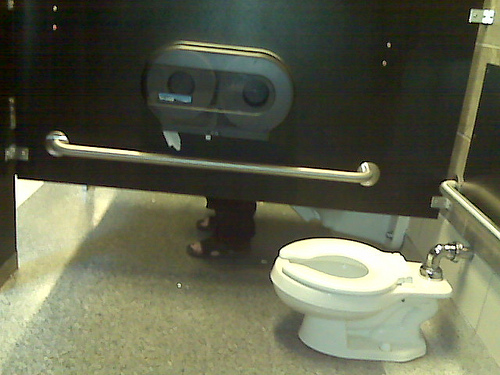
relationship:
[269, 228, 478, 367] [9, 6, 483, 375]
toilet in restroom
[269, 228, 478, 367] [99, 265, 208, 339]
toilet on floor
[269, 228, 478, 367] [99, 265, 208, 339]
toilet near floor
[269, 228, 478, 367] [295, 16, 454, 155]
toilet near wall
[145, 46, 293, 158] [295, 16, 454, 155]
dispenser on wall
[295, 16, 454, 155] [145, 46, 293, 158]
wall near dispenser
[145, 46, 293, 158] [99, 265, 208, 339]
dispenser near floor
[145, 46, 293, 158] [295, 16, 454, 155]
dispenser near wall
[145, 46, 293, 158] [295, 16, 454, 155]
dispenser by wall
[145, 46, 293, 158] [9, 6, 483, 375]
dispenser in restroom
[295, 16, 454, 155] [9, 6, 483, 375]
wall in restroom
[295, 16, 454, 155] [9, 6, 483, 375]
wall of restroom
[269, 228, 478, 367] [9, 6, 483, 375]
toilet of restroom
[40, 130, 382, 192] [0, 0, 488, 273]
rail on wall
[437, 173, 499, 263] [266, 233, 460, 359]
rail behind toilet